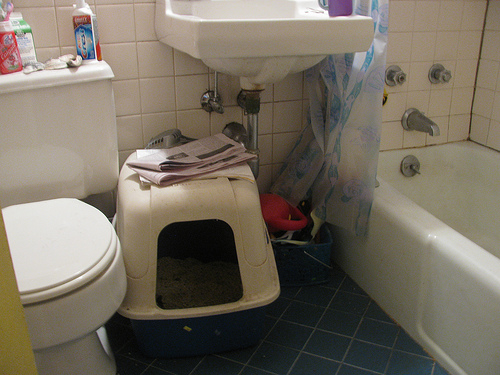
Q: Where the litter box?
A: In the bathroom.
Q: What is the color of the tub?
A: White.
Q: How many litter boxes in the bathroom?
A: One.